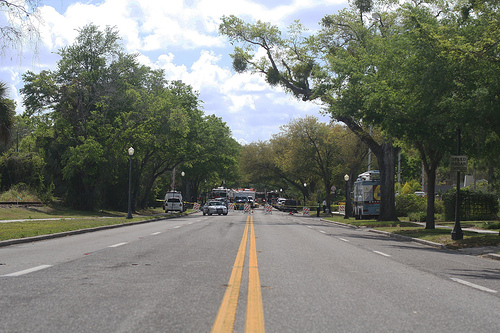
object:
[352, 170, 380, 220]
truck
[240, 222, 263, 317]
lane divider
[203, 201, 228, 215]
police car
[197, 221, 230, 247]
street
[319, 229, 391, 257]
lines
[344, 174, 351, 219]
lamp post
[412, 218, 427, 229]
sidewalk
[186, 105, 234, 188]
trees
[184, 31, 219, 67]
sky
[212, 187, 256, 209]
emergency vehicle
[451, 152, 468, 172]
sign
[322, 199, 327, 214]
man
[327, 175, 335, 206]
tree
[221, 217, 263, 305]
double line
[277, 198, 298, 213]
car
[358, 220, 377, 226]
grass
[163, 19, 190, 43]
clouds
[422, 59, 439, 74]
leaves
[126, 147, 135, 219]
pole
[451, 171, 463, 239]
pole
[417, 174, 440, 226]
tree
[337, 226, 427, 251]
shadow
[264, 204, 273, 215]
barricade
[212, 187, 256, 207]
fire truck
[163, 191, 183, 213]
van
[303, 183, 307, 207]
lamp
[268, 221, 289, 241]
road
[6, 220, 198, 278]
line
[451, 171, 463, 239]
post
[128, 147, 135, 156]
light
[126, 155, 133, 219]
post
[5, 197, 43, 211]
train track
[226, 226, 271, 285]
lines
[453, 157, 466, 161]
lettters